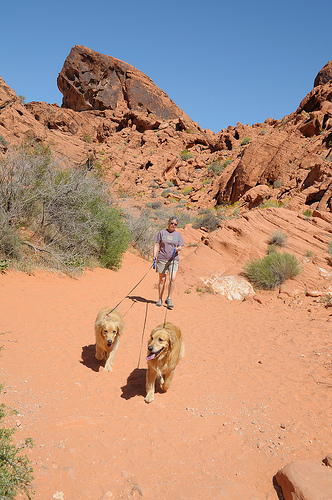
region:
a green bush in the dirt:
[246, 253, 295, 288]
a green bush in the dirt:
[0, 401, 35, 498]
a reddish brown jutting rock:
[57, 43, 195, 130]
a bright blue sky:
[2, 2, 324, 127]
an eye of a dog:
[103, 328, 108, 333]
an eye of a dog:
[112, 329, 116, 335]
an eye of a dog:
[149, 334, 154, 340]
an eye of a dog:
[157, 337, 162, 340]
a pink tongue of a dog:
[146, 351, 156, 359]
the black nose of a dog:
[106, 338, 113, 342]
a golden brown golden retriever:
[142, 320, 183, 403]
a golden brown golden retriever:
[92, 307, 120, 370]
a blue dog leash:
[106, 257, 156, 314]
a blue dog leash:
[165, 247, 174, 329]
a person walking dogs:
[153, 213, 185, 306]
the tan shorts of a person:
[156, 260, 179, 272]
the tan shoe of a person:
[165, 298, 173, 307]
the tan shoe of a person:
[156, 299, 164, 307]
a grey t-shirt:
[156, 230, 181, 260]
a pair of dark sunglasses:
[169, 223, 176, 225]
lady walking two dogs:
[86, 211, 185, 401]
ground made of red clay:
[10, 211, 330, 498]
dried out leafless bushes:
[10, 147, 103, 278]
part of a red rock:
[270, 448, 330, 498]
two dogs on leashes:
[92, 241, 186, 398]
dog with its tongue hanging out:
[140, 324, 172, 390]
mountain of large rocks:
[7, 33, 331, 309]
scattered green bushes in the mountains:
[175, 129, 280, 226]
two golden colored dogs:
[82, 299, 186, 409]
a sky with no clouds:
[6, 5, 323, 153]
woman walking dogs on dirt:
[84, 212, 197, 395]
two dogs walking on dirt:
[76, 293, 195, 398]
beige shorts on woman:
[151, 256, 180, 277]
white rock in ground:
[197, 274, 253, 309]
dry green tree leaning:
[6, 148, 129, 277]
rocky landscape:
[30, 58, 328, 155]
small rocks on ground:
[185, 395, 317, 460]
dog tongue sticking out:
[140, 343, 173, 360]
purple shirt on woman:
[156, 227, 176, 263]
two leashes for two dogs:
[137, 250, 182, 322]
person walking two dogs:
[84, 214, 190, 395]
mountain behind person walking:
[130, 112, 230, 302]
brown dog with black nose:
[146, 320, 182, 387]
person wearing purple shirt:
[143, 209, 189, 287]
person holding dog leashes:
[145, 208, 213, 296]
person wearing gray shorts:
[139, 209, 201, 321]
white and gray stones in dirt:
[18, 389, 96, 487]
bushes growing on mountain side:
[172, 136, 255, 201]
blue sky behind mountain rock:
[57, 34, 159, 126]